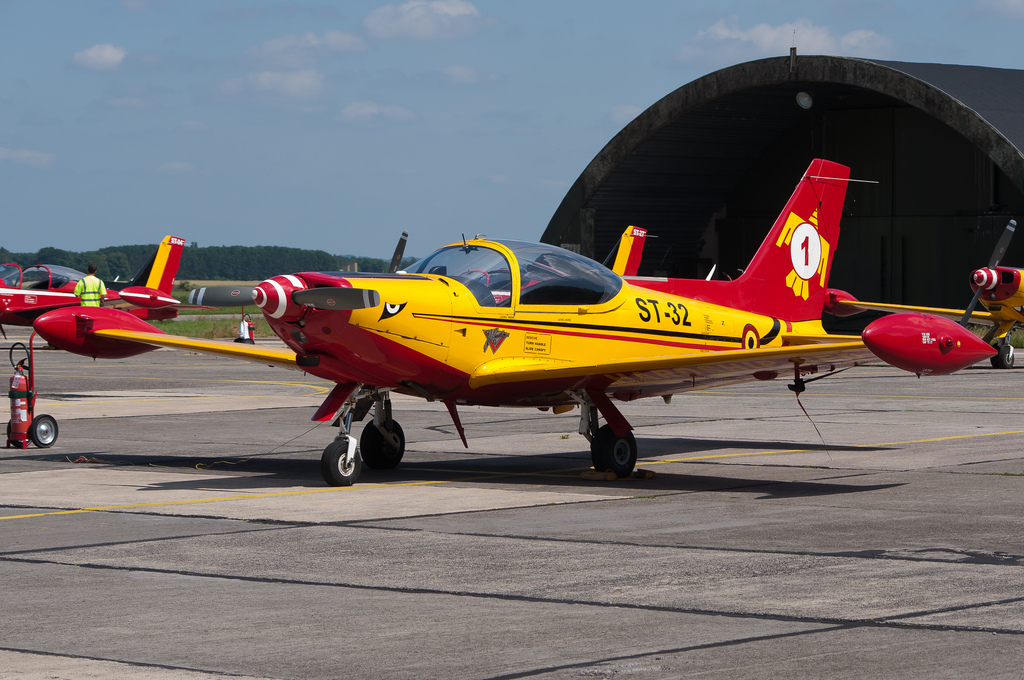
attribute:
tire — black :
[591, 427, 654, 497]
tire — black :
[323, 433, 360, 483]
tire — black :
[362, 414, 406, 479]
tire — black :
[588, 421, 641, 484]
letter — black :
[647, 293, 669, 322]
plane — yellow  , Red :
[76, 146, 995, 492]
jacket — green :
[76, 274, 109, 300]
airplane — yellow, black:
[245, 159, 993, 482]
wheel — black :
[311, 415, 633, 496]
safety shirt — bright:
[71, 279, 108, 301]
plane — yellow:
[125, 186, 973, 588]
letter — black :
[621, 273, 669, 330]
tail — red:
[692, 147, 865, 329]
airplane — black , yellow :
[7, 203, 213, 376]